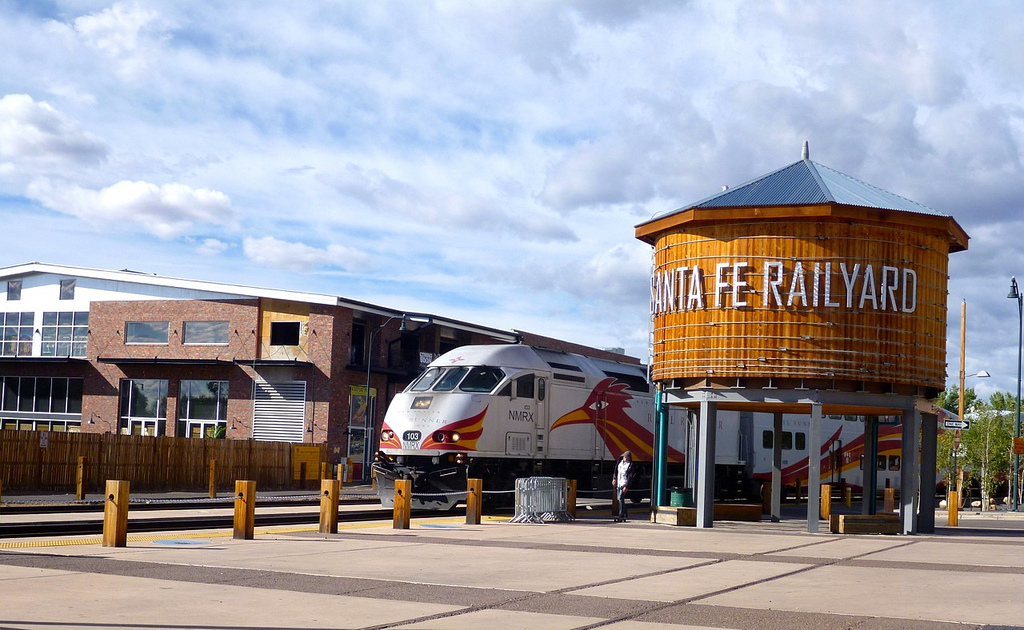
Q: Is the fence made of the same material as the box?
A: No, the fence is made of wood and the box is made of metal.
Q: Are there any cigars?
A: No, there are no cigars.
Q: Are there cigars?
A: No, there are no cigars.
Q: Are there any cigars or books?
A: No, there are no cigars or books.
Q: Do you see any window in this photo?
A: Yes, there is a window.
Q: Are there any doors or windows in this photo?
A: Yes, there is a window.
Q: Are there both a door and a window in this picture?
A: No, there is a window but no doors.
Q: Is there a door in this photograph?
A: No, there are no doors.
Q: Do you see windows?
A: Yes, there is a window.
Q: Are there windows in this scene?
A: Yes, there is a window.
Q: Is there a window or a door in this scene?
A: Yes, there is a window.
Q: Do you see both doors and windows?
A: No, there is a window but no doors.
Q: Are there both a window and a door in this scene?
A: No, there is a window but no doors.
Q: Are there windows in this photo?
A: Yes, there is a window.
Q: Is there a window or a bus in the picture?
A: Yes, there is a window.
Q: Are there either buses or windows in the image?
A: Yes, there is a window.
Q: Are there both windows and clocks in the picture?
A: No, there is a window but no clocks.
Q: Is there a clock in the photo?
A: No, there are no clocks.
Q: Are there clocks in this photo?
A: No, there are no clocks.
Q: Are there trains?
A: Yes, there is a train.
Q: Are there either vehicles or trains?
A: Yes, there is a train.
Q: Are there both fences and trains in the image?
A: Yes, there are both a train and a fence.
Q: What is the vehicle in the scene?
A: The vehicle is a train.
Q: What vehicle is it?
A: The vehicle is a train.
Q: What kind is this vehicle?
A: That is a train.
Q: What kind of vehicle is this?
A: That is a train.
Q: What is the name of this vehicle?
A: That is a train.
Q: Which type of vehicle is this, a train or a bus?
A: That is a train.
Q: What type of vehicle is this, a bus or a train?
A: That is a train.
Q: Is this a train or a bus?
A: This is a train.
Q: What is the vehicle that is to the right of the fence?
A: The vehicle is a train.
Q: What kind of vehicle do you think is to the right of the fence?
A: The vehicle is a train.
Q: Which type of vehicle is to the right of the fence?
A: The vehicle is a train.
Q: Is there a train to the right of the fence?
A: Yes, there is a train to the right of the fence.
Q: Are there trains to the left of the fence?
A: No, the train is to the right of the fence.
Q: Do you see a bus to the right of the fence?
A: No, there is a train to the right of the fence.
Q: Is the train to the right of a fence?
A: Yes, the train is to the right of a fence.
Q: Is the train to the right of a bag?
A: No, the train is to the right of a fence.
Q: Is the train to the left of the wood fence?
A: No, the train is to the right of the fence.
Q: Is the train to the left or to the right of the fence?
A: The train is to the right of the fence.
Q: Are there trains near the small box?
A: Yes, there is a train near the box.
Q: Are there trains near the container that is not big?
A: Yes, there is a train near the box.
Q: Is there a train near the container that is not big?
A: Yes, there is a train near the box.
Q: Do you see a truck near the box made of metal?
A: No, there is a train near the box.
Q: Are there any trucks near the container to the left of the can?
A: No, there is a train near the box.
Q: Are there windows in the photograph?
A: Yes, there is a window.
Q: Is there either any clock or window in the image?
A: Yes, there is a window.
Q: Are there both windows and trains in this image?
A: Yes, there are both a window and a train.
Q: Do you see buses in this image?
A: No, there are no buses.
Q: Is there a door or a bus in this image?
A: No, there are no buses or doors.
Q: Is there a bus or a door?
A: No, there are no buses or doors.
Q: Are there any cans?
A: Yes, there is a can.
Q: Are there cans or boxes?
A: Yes, there is a can.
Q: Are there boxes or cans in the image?
A: Yes, there is a can.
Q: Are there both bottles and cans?
A: No, there is a can but no bottles.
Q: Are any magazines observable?
A: No, there are no magazines.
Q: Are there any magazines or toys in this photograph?
A: No, there are no magazines or toys.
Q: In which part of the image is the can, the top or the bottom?
A: The can is in the bottom of the image.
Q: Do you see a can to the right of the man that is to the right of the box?
A: Yes, there is a can to the right of the man.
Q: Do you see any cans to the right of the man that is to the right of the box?
A: Yes, there is a can to the right of the man.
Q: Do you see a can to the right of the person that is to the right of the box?
A: Yes, there is a can to the right of the man.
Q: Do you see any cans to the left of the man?
A: No, the can is to the right of the man.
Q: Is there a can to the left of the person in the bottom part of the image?
A: No, the can is to the right of the man.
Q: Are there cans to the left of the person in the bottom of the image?
A: No, the can is to the right of the man.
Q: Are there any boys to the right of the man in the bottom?
A: No, there is a can to the right of the man.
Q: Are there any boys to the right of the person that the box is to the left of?
A: No, there is a can to the right of the man.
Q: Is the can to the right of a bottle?
A: No, the can is to the right of the man.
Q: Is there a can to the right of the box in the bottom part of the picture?
A: Yes, there is a can to the right of the box.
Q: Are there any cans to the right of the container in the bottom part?
A: Yes, there is a can to the right of the box.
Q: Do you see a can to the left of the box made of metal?
A: No, the can is to the right of the box.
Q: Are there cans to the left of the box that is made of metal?
A: No, the can is to the right of the box.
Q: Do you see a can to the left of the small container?
A: No, the can is to the right of the box.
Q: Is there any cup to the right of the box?
A: No, there is a can to the right of the box.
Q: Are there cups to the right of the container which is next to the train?
A: No, there is a can to the right of the box.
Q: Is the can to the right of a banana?
A: No, the can is to the right of a box.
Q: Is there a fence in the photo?
A: Yes, there is a fence.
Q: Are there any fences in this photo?
A: Yes, there is a fence.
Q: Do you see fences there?
A: Yes, there is a fence.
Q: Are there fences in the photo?
A: Yes, there is a fence.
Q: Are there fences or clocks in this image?
A: Yes, there is a fence.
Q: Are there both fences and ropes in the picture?
A: No, there is a fence but no ropes.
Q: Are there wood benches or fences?
A: Yes, there is a wood fence.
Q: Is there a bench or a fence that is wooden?
A: Yes, the fence is wooden.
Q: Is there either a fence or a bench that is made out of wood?
A: Yes, the fence is made of wood.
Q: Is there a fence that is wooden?
A: Yes, there is a fence that is wooden.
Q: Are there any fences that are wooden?
A: Yes, there is a fence that is wooden.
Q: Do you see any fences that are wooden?
A: Yes, there is a fence that is wooden.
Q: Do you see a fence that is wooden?
A: Yes, there is a fence that is wooden.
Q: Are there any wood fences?
A: Yes, there is a fence that is made of wood.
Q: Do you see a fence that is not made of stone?
A: Yes, there is a fence that is made of wood.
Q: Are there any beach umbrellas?
A: No, there are no beach umbrellas.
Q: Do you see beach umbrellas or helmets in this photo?
A: No, there are no beach umbrellas or helmets.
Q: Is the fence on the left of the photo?
A: Yes, the fence is on the left of the image.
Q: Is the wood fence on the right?
A: No, the fence is on the left of the image.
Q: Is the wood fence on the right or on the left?
A: The fence is on the left of the image.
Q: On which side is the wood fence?
A: The fence is on the left of the image.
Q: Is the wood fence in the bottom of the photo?
A: Yes, the fence is in the bottom of the image.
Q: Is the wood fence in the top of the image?
A: No, the fence is in the bottom of the image.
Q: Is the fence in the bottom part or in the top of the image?
A: The fence is in the bottom of the image.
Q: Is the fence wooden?
A: Yes, the fence is wooden.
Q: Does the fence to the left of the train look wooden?
A: Yes, the fence is wooden.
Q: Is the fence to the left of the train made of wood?
A: Yes, the fence is made of wood.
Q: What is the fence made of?
A: The fence is made of wood.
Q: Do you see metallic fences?
A: No, there is a fence but it is wooden.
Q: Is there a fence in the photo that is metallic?
A: No, there is a fence but it is wooden.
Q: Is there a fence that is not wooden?
A: No, there is a fence but it is wooden.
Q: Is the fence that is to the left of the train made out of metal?
A: No, the fence is made of wood.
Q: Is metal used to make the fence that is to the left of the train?
A: No, the fence is made of wood.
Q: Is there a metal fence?
A: No, there is a fence but it is made of wood.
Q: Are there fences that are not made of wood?
A: No, there is a fence but it is made of wood.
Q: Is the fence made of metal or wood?
A: The fence is made of wood.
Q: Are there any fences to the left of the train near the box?
A: Yes, there is a fence to the left of the train.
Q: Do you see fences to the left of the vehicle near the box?
A: Yes, there is a fence to the left of the train.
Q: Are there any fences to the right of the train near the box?
A: No, the fence is to the left of the train.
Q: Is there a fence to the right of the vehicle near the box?
A: No, the fence is to the left of the train.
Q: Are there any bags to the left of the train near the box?
A: No, there is a fence to the left of the train.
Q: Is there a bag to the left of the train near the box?
A: No, there is a fence to the left of the train.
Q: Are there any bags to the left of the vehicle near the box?
A: No, there is a fence to the left of the train.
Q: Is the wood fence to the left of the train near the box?
A: Yes, the fence is to the left of the train.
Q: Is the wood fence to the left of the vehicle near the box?
A: Yes, the fence is to the left of the train.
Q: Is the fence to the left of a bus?
A: No, the fence is to the left of the train.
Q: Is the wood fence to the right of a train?
A: No, the fence is to the left of a train.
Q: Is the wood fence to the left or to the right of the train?
A: The fence is to the left of the train.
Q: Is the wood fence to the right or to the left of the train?
A: The fence is to the left of the train.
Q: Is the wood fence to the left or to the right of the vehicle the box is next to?
A: The fence is to the left of the train.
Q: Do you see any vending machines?
A: No, there are no vending machines.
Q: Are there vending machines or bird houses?
A: No, there are no vending machines or bird houses.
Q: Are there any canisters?
A: No, there are no canisters.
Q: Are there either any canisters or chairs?
A: No, there are no canisters or chairs.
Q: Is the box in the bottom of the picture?
A: Yes, the box is in the bottom of the image.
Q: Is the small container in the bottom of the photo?
A: Yes, the box is in the bottom of the image.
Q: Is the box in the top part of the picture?
A: No, the box is in the bottom of the image.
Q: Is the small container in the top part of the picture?
A: No, the box is in the bottom of the image.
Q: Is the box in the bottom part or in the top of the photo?
A: The box is in the bottom of the image.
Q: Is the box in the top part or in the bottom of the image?
A: The box is in the bottom of the image.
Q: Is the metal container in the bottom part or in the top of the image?
A: The box is in the bottom of the image.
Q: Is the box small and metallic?
A: Yes, the box is small and metallic.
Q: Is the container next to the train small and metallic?
A: Yes, the box is small and metallic.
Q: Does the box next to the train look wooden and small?
A: No, the box is small but metallic.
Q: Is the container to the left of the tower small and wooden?
A: No, the box is small but metallic.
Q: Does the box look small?
A: Yes, the box is small.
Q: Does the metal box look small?
A: Yes, the box is small.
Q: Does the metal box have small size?
A: Yes, the box is small.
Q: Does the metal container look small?
A: Yes, the box is small.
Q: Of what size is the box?
A: The box is small.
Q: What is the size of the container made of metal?
A: The box is small.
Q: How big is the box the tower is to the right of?
A: The box is small.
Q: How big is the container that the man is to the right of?
A: The box is small.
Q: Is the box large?
A: No, the box is small.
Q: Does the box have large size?
A: No, the box is small.